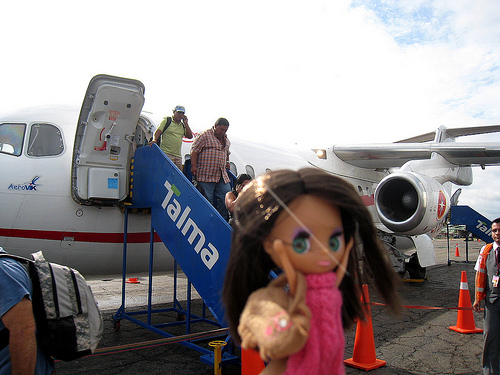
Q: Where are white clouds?
A: In the sky.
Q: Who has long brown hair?
A: The doll.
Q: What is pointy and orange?
A: Traffic cones.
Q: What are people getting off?
A: A plane.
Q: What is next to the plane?
A: Stairs.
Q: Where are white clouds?
A: In the sky.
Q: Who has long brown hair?
A: Doll.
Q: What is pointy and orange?
A: Traffic cones.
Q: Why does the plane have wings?
A: To fly.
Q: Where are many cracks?
A: On the ground.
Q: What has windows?
A: The plane.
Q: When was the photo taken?
A: During the daytime.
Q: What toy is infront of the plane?
A: A doll.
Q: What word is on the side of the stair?
A: Talma.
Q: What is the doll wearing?
A: A pink dress.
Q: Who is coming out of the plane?
A: Passengers.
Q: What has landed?
A: The airplane.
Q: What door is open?
A: The plane door.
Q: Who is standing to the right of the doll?
A: The employee.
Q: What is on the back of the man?
A: A backpack.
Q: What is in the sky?
A: Clouds.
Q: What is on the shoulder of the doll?
A: A purse.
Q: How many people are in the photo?
A: Five.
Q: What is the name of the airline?
A: Talma.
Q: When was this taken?
A: Daytime.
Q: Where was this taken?
A: Airport.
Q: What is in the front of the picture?
A: Doll.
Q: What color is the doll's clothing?
A: Pink.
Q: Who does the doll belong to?
A: A child.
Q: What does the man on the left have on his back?
A: Backpack.